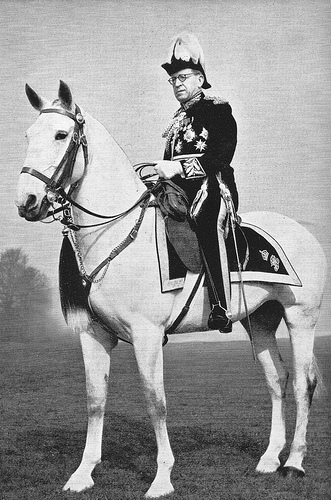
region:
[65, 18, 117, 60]
this is the wall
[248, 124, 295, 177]
the wall is clean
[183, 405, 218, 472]
this is the grass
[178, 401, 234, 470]
the grass is short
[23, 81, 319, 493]
this is a horse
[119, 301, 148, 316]
the fur is white in color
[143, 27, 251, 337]
this is a man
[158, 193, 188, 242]
this is a saddle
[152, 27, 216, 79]
this is a cap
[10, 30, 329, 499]
Old photo of a military man and his horse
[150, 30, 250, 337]
Man in uniform on the white horse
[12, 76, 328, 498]
White horse that the man in uniform is riding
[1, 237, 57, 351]
Tree to the left of the man on the horse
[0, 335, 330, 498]
Grassy area the the horse is standing on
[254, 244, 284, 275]
Emblem on the horse blanket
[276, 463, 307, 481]
Only black hoof on the horse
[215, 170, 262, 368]
Saber on the side of the man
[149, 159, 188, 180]
Gloved left hand of the man on the horse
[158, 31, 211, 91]
Military hat of the man on the horse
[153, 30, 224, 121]
Head of a person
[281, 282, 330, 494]
Leg of a horse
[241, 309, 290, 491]
Leg of a horse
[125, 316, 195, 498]
Leg of a horse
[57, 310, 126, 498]
Leg of a horse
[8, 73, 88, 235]
Head of a horse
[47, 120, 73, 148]
Eye of a horse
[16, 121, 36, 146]
Eye of a horse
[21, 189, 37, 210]
Nose of a horse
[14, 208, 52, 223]
Mouth of a horse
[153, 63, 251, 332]
the man has glasses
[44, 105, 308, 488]
the horse is white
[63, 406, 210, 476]
shadow is on the ground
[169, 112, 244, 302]
the uniform is black and white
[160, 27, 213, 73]
top of the hat is white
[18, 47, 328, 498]
the picture is black and white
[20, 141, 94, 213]
horse strap is around the mouth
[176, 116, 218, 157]
stars are on the unifrom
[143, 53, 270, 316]
the guy is on the horse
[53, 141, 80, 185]
the strap is leather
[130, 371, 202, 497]
the horses leg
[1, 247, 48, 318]
a tree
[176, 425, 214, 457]
shadow on the grass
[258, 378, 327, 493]
the horses back legs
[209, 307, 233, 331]
the mans shoe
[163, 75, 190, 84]
man is wearing glasses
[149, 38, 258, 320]
man is sitting on the horse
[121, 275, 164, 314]
the horse is white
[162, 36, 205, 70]
man is wearing a hat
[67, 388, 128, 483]
the horses front leg